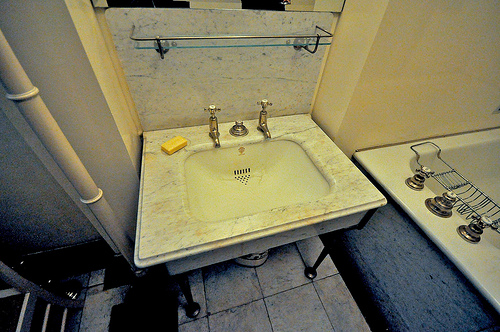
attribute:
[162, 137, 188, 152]
soap — yellow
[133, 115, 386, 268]
sink — marble, white, granite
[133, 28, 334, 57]
shelf — glass, metal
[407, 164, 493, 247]
faucets — silver, white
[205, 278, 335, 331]
tile — marble, white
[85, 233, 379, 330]
floor — tiled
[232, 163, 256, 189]
drain — triangle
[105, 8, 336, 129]
backsplash — marble, white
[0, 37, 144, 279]
pipe — white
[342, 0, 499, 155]
wall — white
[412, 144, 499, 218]
rack — metal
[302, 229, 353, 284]
leg — metal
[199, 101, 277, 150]
faucets — silver